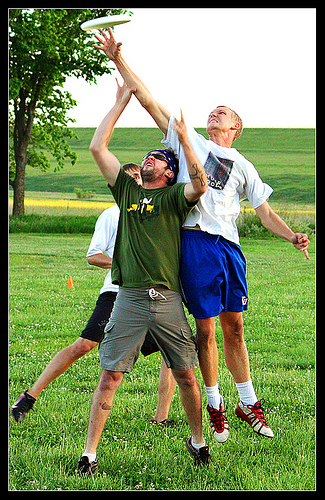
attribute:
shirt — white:
[83, 201, 124, 296]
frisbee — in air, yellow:
[77, 15, 129, 29]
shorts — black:
[79, 292, 162, 351]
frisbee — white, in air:
[78, 13, 132, 31]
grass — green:
[7, 127, 314, 491]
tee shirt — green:
[107, 165, 189, 289]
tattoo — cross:
[190, 165, 207, 189]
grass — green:
[266, 134, 321, 175]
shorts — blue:
[175, 222, 252, 317]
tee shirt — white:
[160, 111, 274, 244]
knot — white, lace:
[146, 287, 164, 297]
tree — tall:
[3, 6, 132, 211]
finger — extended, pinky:
[298, 245, 311, 258]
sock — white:
[235, 380, 259, 404]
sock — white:
[205, 384, 222, 407]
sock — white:
[189, 436, 203, 449]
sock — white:
[81, 450, 96, 461]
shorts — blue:
[169, 221, 252, 324]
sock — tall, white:
[229, 378, 259, 408]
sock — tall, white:
[201, 378, 227, 415]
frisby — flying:
[81, 14, 133, 30]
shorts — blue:
[177, 227, 248, 317]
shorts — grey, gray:
[95, 285, 202, 370]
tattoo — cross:
[187, 160, 205, 192]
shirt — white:
[84, 196, 130, 295]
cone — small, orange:
[54, 268, 81, 297]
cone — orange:
[63, 276, 84, 295]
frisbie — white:
[80, 14, 131, 30]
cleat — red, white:
[205, 394, 232, 446]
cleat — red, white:
[234, 397, 275, 438]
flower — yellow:
[33, 204, 38, 205]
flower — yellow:
[53, 199, 55, 201]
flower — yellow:
[83, 202, 84, 203]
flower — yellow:
[98, 204, 99, 205]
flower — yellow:
[26, 199, 27, 200]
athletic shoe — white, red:
[205, 394, 231, 443]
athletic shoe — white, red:
[234, 395, 276, 438]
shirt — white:
[83, 200, 119, 292]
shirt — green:
[105, 164, 200, 290]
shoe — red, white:
[205, 394, 231, 444]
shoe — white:
[234, 398, 274, 438]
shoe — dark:
[72, 455, 100, 478]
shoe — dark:
[182, 436, 214, 466]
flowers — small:
[128, 476, 159, 489]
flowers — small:
[274, 404, 294, 422]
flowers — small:
[15, 346, 35, 364]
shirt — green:
[116, 185, 178, 284]